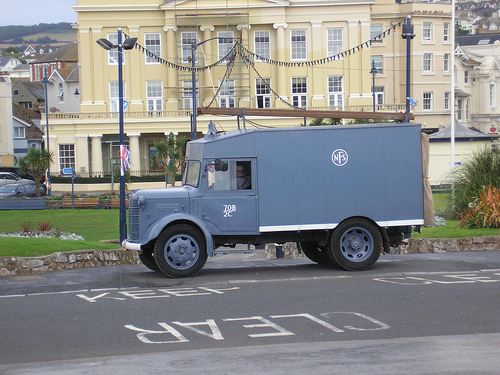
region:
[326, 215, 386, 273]
the back wheels of the truck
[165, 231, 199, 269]
the blue rim on the tire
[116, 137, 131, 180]
the flag on the pole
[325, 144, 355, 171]
the white logo on the truck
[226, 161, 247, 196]
the driver fo the truck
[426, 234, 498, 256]
the stone step behind the truck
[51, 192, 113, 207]
the brown bench in the distance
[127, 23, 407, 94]
the rope flags on the light posts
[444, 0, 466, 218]
the white pole in the grass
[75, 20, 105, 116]
the coulmns on the building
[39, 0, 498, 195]
a pale yellow building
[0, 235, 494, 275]
a low stone wall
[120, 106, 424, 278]
a light blue truck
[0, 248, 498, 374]
pavement with words written on it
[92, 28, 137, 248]
a blue street light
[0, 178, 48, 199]
a grey car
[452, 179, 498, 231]
an orange bush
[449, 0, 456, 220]
a tall white pole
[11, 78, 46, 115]
a dark grey house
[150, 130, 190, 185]
an interesting spiky green tree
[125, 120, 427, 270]
Slate blue armored truck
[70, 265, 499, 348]
Words on white on the road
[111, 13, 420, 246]
Three metal blue poles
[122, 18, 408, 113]
Four hanging strings of lights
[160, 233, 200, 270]
Blue wheel tire rims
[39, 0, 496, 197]
Large cream colored building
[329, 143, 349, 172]
White logo on a blue truck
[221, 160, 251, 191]
Person in grey driving a truck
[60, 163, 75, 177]
Blue and white sign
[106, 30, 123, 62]
glass window on building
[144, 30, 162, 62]
glass window on building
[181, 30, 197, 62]
glass window on building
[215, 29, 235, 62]
glass window on building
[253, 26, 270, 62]
glass window on building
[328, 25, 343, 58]
glass window on building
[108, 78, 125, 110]
glass window on building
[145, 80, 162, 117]
glass window on building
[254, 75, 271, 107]
glass window on building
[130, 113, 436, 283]
a gray truck in the road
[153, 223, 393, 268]
tires on a truck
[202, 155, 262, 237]
a door on a truck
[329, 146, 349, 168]
white letters on a gray truck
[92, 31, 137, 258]
lights on a pole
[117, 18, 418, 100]
Christmas lights hanging on poles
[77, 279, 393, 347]
words on a street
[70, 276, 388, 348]
words that say Keep Clear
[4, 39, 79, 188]
houses in the distance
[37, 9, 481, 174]
a large building in the distance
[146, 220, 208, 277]
a tire of a blue van truck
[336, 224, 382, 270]
a tire of a blue van truck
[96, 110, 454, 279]
a blue van truck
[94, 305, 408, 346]
writing on the pavement that says CLEAR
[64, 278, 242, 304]
writing on the pavement that says KEEP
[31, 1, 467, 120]
a large yellow building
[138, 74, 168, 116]
a white window on a building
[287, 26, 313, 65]
writing on the pavement that says CLEAR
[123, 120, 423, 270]
Grey truck With an NFS logo on the side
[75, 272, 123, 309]
K painted on the road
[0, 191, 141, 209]
benches across the grass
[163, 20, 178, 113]
greek styled column on a yellow building